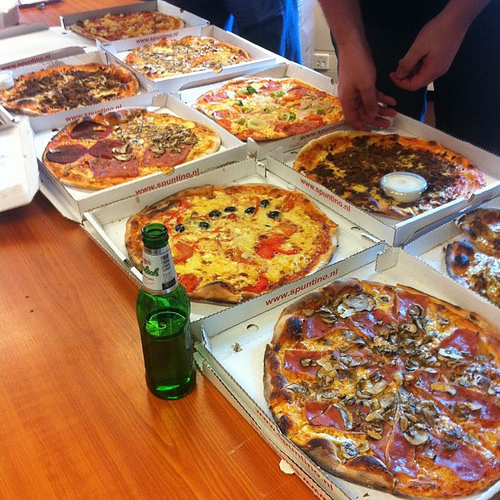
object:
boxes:
[193, 247, 499, 422]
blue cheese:
[386, 173, 424, 191]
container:
[380, 171, 428, 204]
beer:
[136, 222, 197, 401]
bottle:
[134, 223, 195, 399]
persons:
[320, 2, 499, 158]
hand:
[338, 51, 396, 134]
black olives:
[174, 223, 186, 232]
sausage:
[11, 72, 122, 104]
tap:
[278, 460, 295, 475]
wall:
[314, 0, 366, 53]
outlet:
[308, 47, 337, 72]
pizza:
[291, 129, 487, 221]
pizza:
[41, 107, 221, 191]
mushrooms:
[112, 118, 196, 162]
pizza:
[194, 77, 348, 142]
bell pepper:
[230, 74, 326, 129]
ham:
[91, 154, 142, 177]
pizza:
[261, 276, 500, 500]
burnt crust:
[264, 275, 500, 497]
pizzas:
[19, 1, 493, 480]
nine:
[0, 1, 497, 500]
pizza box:
[77, 160, 389, 334]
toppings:
[123, 115, 199, 155]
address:
[263, 268, 341, 306]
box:
[83, 158, 384, 340]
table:
[0, 271, 120, 496]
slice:
[322, 277, 396, 362]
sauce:
[328, 150, 373, 188]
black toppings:
[198, 221, 209, 229]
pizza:
[67, 10, 183, 40]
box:
[60, 0, 211, 48]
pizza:
[123, 35, 248, 79]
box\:
[102, 24, 276, 89]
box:
[265, 107, 499, 246]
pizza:
[443, 207, 498, 312]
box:
[400, 191, 498, 310]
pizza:
[0, 63, 138, 121]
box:
[0, 46, 159, 129]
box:
[21, 89, 249, 214]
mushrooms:
[398, 404, 433, 448]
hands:
[390, 27, 463, 92]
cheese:
[138, 41, 246, 66]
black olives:
[266, 209, 281, 220]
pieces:
[254, 234, 302, 259]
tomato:
[243, 277, 269, 294]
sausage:
[307, 127, 456, 206]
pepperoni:
[285, 293, 500, 480]